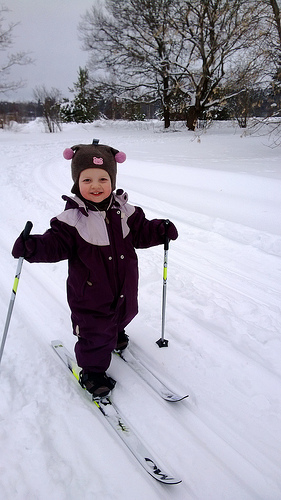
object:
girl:
[12, 136, 178, 399]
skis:
[49, 337, 182, 484]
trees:
[60, 60, 102, 123]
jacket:
[21, 185, 169, 308]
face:
[79, 166, 112, 202]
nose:
[91, 182, 101, 190]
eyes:
[81, 176, 92, 184]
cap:
[63, 138, 126, 194]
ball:
[63, 147, 74, 159]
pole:
[161, 220, 167, 345]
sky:
[0, 0, 280, 117]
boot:
[78, 361, 117, 396]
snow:
[0, 114, 281, 499]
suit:
[11, 189, 177, 373]